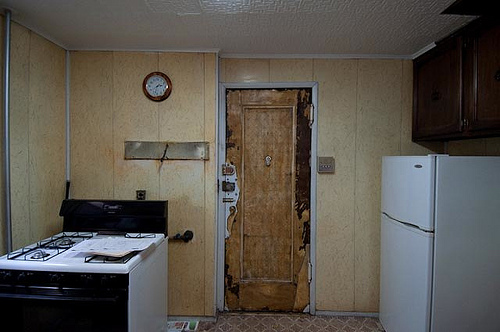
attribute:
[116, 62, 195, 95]
clock — wooden, hanging, round, battery, white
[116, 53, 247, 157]
wall — beige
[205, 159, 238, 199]
locks — 3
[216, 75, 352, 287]
door — damaged, brown, fragmented, broken, worn out, locking, old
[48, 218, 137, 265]
stove — here, white, black, gas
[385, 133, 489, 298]
fridge — white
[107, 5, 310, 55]
ceiling — tile, white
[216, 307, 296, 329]
floor — beige, plastic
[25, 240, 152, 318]
range — inside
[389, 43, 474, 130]
cupboards — inside, brown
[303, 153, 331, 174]
switches — inside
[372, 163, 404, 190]
door — white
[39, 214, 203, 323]
cooker — large, black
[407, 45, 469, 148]
cabinets — overhead